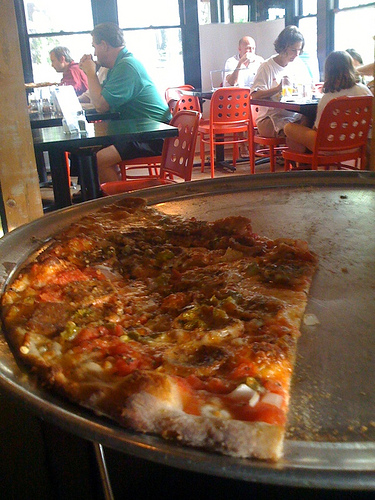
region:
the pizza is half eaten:
[16, 198, 306, 463]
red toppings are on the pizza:
[64, 241, 217, 355]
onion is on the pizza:
[226, 368, 272, 408]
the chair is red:
[312, 106, 368, 164]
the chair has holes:
[210, 91, 249, 126]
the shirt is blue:
[97, 61, 167, 124]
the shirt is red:
[63, 66, 86, 85]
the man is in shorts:
[64, 31, 179, 169]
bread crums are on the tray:
[287, 372, 346, 432]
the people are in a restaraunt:
[40, 25, 372, 165]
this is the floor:
[196, 167, 207, 177]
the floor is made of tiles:
[196, 170, 204, 179]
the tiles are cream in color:
[200, 169, 206, 177]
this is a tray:
[309, 367, 351, 415]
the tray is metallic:
[326, 355, 351, 391]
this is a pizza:
[14, 217, 306, 410]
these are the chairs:
[168, 104, 275, 169]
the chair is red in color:
[221, 109, 229, 119]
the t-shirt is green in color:
[118, 65, 148, 106]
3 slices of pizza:
[6, 192, 319, 485]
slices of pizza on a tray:
[0, 178, 369, 494]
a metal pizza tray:
[1, 152, 371, 498]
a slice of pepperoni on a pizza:
[144, 336, 251, 386]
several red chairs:
[160, 74, 365, 175]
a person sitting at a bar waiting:
[69, 23, 185, 182]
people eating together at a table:
[257, 19, 370, 163]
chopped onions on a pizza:
[224, 375, 284, 419]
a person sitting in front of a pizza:
[16, 32, 87, 109]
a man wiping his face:
[212, 35, 269, 104]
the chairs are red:
[176, 90, 251, 174]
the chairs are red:
[165, 78, 255, 155]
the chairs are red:
[166, 83, 256, 174]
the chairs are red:
[162, 70, 250, 183]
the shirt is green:
[98, 48, 173, 150]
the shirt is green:
[92, 55, 172, 138]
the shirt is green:
[92, 61, 168, 138]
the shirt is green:
[94, 57, 185, 152]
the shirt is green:
[81, 53, 177, 133]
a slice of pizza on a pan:
[76, 239, 373, 481]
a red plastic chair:
[200, 91, 252, 161]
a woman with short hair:
[277, 22, 305, 63]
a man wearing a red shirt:
[58, 51, 84, 96]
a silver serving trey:
[0, 164, 373, 498]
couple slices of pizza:
[2, 198, 318, 470]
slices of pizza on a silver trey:
[0, 168, 373, 498]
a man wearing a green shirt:
[77, 23, 165, 179]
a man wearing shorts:
[77, 23, 160, 177]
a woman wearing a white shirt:
[250, 23, 306, 138]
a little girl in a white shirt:
[284, 52, 374, 168]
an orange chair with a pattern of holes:
[101, 113, 208, 193]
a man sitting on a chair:
[77, 15, 172, 181]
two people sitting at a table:
[249, 30, 374, 169]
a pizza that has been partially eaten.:
[5, 174, 373, 482]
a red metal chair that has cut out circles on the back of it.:
[200, 85, 253, 177]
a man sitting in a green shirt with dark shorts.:
[75, 20, 176, 177]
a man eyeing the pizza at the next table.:
[19, 19, 174, 119]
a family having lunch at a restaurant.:
[252, 24, 373, 116]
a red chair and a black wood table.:
[29, 107, 202, 201]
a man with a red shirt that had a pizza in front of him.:
[22, 45, 88, 120]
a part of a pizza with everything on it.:
[4, 240, 317, 463]